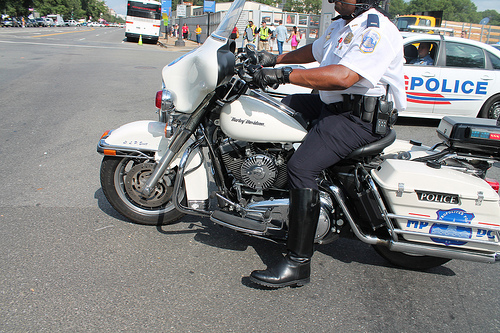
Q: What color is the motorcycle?
A: White.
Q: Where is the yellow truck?
A: On the right side of the picture.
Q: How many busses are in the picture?
A: One.